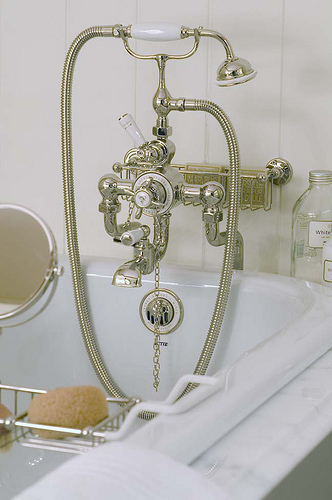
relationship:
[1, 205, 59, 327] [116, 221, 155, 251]
mirror by tap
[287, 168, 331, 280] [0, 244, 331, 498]
bottle by tub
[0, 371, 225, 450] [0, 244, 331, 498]
rack on tub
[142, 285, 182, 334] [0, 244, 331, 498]
drain on tub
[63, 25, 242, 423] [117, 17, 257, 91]
hose connected to spigot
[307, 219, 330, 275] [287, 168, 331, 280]
label on bottle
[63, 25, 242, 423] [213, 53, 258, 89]
hose on shower head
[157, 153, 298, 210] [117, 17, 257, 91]
tray behind spigot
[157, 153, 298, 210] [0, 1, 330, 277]
tray on wall